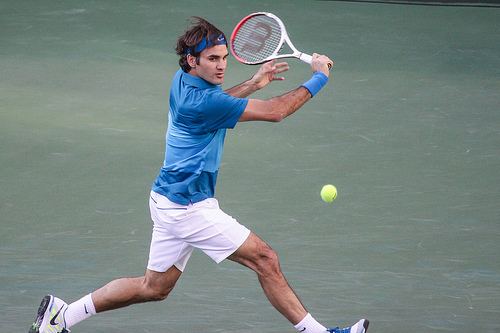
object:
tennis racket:
[232, 10, 316, 66]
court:
[0, 1, 496, 332]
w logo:
[238, 22, 272, 56]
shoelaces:
[328, 325, 351, 333]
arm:
[225, 56, 289, 97]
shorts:
[147, 189, 252, 273]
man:
[23, 10, 369, 332]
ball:
[317, 182, 339, 203]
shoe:
[30, 295, 67, 332]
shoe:
[328, 317, 369, 331]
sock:
[65, 292, 97, 327]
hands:
[254, 53, 337, 89]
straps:
[157, 112, 232, 179]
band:
[300, 71, 332, 99]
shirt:
[150, 69, 249, 204]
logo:
[48, 302, 64, 325]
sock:
[293, 311, 325, 331]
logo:
[81, 303, 89, 313]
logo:
[298, 327, 308, 332]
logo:
[209, 34, 223, 41]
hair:
[175, 15, 227, 73]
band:
[188, 36, 226, 53]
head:
[177, 14, 231, 84]